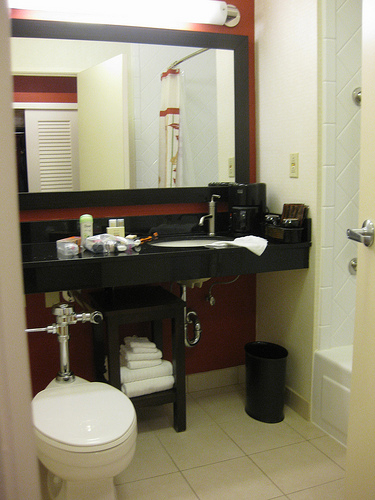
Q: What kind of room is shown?
A: It is a bathroom.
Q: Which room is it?
A: It is a bathroom.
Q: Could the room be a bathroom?
A: Yes, it is a bathroom.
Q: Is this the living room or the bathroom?
A: It is the bathroom.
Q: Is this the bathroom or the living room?
A: It is the bathroom.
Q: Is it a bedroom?
A: No, it is a bathroom.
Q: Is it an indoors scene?
A: Yes, it is indoors.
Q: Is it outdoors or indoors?
A: It is indoors.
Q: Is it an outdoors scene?
A: No, it is indoors.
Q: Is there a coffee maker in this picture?
A: Yes, there is a coffee maker.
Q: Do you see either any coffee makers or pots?
A: Yes, there is a coffee maker.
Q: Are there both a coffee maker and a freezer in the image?
A: No, there is a coffee maker but no refrigerators.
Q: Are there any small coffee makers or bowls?
A: Yes, there is a small coffee maker.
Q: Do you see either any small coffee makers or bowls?
A: Yes, there is a small coffee maker.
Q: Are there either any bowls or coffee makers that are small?
A: Yes, the coffee maker is small.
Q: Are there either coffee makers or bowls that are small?
A: Yes, the coffee maker is small.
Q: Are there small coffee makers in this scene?
A: Yes, there is a small coffee maker.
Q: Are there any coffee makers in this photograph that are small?
A: Yes, there is a coffee maker that is small.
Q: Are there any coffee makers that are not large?
A: Yes, there is a small coffee maker.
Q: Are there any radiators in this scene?
A: No, there are no radiators.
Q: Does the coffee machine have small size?
A: Yes, the coffee machine is small.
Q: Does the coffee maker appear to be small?
A: Yes, the coffee maker is small.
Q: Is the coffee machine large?
A: No, the coffee machine is small.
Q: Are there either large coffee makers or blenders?
A: No, there is a coffee maker but it is small.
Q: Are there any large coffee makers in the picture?
A: No, there is a coffee maker but it is small.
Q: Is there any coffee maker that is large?
A: No, there is a coffee maker but it is small.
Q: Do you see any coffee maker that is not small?
A: No, there is a coffee maker but it is small.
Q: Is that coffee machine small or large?
A: The coffee machine is small.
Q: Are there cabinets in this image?
A: No, there are no cabinets.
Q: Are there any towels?
A: Yes, there is a towel.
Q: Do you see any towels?
A: Yes, there is a towel.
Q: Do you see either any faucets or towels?
A: Yes, there is a towel.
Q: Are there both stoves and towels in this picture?
A: No, there is a towel but no stoves.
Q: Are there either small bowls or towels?
A: Yes, there is a small towel.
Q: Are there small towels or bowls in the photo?
A: Yes, there is a small towel.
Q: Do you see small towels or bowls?
A: Yes, there is a small towel.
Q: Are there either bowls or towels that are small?
A: Yes, the towel is small.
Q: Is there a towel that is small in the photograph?
A: Yes, there is a small towel.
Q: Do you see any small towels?
A: Yes, there is a small towel.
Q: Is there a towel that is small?
A: Yes, there is a towel that is small.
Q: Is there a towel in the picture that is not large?
A: Yes, there is a small towel.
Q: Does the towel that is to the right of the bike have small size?
A: Yes, the towel is small.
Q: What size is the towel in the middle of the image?
A: The towel is small.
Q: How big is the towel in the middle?
A: The towel is small.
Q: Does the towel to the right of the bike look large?
A: No, the towel is small.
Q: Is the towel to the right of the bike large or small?
A: The towel is small.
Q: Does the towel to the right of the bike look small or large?
A: The towel is small.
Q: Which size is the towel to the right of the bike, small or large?
A: The towel is small.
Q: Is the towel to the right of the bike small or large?
A: The towel is small.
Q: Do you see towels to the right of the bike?
A: Yes, there is a towel to the right of the bike.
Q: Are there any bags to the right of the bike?
A: No, there is a towel to the right of the bike.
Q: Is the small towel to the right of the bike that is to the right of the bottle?
A: Yes, the towel is to the right of the bike.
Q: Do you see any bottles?
A: Yes, there is a bottle.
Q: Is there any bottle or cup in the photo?
A: Yes, there is a bottle.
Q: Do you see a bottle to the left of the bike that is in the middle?
A: Yes, there is a bottle to the left of the bike.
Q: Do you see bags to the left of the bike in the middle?
A: No, there is a bottle to the left of the bike.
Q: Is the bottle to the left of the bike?
A: Yes, the bottle is to the left of the bike.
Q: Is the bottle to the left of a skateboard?
A: No, the bottle is to the left of the bike.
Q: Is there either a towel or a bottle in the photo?
A: Yes, there is a towel.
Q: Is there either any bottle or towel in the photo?
A: Yes, there is a towel.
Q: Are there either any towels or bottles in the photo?
A: Yes, there is a towel.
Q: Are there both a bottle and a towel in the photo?
A: Yes, there are both a towel and a bottle.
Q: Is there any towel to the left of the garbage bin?
A: Yes, there is a towel to the left of the garbage bin.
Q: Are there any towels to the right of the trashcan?
A: No, the towel is to the left of the trashcan.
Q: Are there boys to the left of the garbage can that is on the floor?
A: No, there is a towel to the left of the trash can.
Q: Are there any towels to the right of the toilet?
A: Yes, there is a towel to the right of the toilet.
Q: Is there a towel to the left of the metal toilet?
A: No, the towel is to the right of the toilet.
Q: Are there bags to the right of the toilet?
A: No, there is a towel to the right of the toilet.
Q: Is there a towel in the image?
A: Yes, there is a towel.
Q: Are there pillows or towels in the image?
A: Yes, there is a towel.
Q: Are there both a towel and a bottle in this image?
A: Yes, there are both a towel and a bottle.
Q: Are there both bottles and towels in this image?
A: Yes, there are both a towel and a bottle.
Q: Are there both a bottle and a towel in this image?
A: Yes, there are both a towel and a bottle.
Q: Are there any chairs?
A: No, there are no chairs.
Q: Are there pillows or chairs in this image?
A: No, there are no chairs or pillows.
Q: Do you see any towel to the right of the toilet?
A: Yes, there is a towel to the right of the toilet.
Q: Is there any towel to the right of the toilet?
A: Yes, there is a towel to the right of the toilet.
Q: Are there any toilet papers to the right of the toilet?
A: No, there is a towel to the right of the toilet.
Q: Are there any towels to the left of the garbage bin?
A: Yes, there is a towel to the left of the garbage bin.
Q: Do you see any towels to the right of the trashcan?
A: No, the towel is to the left of the trashcan.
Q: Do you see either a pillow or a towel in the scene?
A: Yes, there is a towel.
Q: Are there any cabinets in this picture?
A: No, there are no cabinets.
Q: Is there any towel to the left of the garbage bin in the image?
A: Yes, there is a towel to the left of the garbage bin.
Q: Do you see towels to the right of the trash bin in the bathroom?
A: No, the towel is to the left of the trashcan.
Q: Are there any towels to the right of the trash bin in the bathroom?
A: No, the towel is to the left of the trashcan.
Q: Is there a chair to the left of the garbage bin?
A: No, there is a towel to the left of the garbage bin.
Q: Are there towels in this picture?
A: Yes, there is a towel.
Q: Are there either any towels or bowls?
A: Yes, there is a towel.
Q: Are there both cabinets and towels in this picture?
A: No, there is a towel but no cabinets.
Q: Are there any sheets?
A: No, there are no sheets.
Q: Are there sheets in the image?
A: No, there are no sheets.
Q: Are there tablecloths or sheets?
A: No, there are no sheets or tablecloths.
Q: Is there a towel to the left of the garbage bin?
A: Yes, there is a towel to the left of the garbage bin.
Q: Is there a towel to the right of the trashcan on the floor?
A: No, the towel is to the left of the garbage bin.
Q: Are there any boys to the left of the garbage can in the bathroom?
A: No, there is a towel to the left of the trashcan.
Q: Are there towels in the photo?
A: Yes, there is a towel.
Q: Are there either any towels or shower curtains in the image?
A: Yes, there is a towel.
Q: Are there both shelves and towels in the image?
A: Yes, there are both a towel and a shelf.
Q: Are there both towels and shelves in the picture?
A: Yes, there are both a towel and a shelf.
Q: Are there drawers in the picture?
A: No, there are no drawers.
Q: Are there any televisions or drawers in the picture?
A: No, there are no drawers or televisions.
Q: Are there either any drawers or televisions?
A: No, there are no drawers or televisions.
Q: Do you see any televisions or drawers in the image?
A: No, there are no drawers or televisions.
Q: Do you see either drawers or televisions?
A: No, there are no drawers or televisions.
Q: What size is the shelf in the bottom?
A: The shelf is small.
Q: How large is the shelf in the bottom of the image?
A: The shelf is small.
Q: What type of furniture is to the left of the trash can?
A: The piece of furniture is a shelf.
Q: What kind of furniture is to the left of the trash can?
A: The piece of furniture is a shelf.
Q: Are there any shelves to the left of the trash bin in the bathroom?
A: Yes, there is a shelf to the left of the trash bin.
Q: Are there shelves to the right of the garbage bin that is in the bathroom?
A: No, the shelf is to the left of the trash can.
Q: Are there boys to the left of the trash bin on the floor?
A: No, there is a shelf to the left of the garbage bin.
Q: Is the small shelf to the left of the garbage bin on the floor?
A: Yes, the shelf is to the left of the garbage can.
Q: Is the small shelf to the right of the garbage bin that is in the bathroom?
A: No, the shelf is to the left of the trash can.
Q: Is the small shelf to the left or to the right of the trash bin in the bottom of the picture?
A: The shelf is to the left of the garbage bin.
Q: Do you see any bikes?
A: Yes, there is a bike.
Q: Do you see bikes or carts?
A: Yes, there is a bike.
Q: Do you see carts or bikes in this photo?
A: Yes, there is a bike.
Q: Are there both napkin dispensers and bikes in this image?
A: No, there is a bike but no napkin dispensers.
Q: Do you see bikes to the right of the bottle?
A: Yes, there is a bike to the right of the bottle.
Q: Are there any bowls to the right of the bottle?
A: No, there is a bike to the right of the bottle.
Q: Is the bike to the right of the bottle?
A: Yes, the bike is to the right of the bottle.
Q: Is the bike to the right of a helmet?
A: No, the bike is to the right of the bottle.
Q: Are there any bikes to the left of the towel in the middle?
A: Yes, there is a bike to the left of the towel.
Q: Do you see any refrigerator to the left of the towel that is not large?
A: No, there is a bike to the left of the towel.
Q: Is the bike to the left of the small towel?
A: Yes, the bike is to the left of the towel.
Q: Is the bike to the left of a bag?
A: No, the bike is to the left of the towel.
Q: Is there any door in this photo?
A: Yes, there is a door.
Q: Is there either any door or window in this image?
A: Yes, there is a door.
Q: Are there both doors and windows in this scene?
A: No, there is a door but no windows.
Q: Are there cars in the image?
A: No, there are no cars.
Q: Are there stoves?
A: No, there are no stoves.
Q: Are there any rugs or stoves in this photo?
A: No, there are no stoves or rugs.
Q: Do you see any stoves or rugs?
A: No, there are no stoves or rugs.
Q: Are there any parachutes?
A: No, there are no parachutes.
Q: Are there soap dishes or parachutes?
A: No, there are no parachutes or soap dishes.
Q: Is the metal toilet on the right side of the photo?
A: No, the toilet is on the left of the image.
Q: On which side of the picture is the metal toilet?
A: The toilet is on the left of the image.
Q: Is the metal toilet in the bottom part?
A: Yes, the toilet is in the bottom of the image.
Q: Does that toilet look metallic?
A: Yes, the toilet is metallic.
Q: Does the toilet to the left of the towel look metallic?
A: Yes, the toilet is metallic.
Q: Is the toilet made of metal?
A: Yes, the toilet is made of metal.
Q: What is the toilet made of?
A: The toilet is made of metal.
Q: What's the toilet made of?
A: The toilet is made of metal.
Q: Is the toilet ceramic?
A: No, the toilet is metallic.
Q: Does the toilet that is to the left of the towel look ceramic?
A: No, the toilet is metallic.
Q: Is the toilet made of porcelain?
A: No, the toilet is made of metal.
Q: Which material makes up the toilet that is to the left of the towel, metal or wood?
A: The toilet is made of metal.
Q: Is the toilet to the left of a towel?
A: Yes, the toilet is to the left of a towel.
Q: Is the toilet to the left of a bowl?
A: No, the toilet is to the left of a towel.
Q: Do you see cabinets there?
A: No, there are no cabinets.